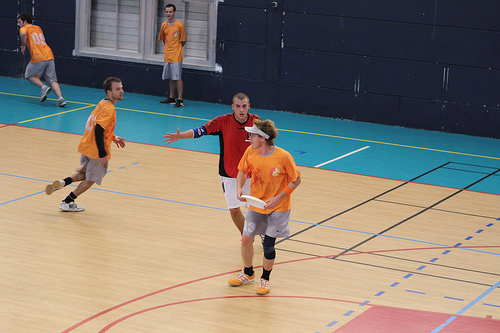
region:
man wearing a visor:
[227, 122, 307, 318]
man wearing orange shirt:
[226, 120, 296, 300]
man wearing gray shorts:
[230, 120, 305, 300]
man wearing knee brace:
[215, 111, 315, 311]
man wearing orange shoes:
[226, 122, 297, 292]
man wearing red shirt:
[177, 100, 232, 225]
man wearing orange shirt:
[45, 70, 137, 260]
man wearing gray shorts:
[33, 72, 133, 210]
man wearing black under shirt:
[46, 66, 124, 241]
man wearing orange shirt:
[140, 5, 200, 112]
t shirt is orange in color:
[231, 149, 310, 209]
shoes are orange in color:
[234, 262, 290, 302]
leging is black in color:
[253, 228, 295, 261]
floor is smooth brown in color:
[98, 230, 169, 302]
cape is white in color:
[246, 114, 274, 146]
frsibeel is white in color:
[232, 184, 261, 214]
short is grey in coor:
[65, 159, 120, 184]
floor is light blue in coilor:
[366, 138, 397, 170]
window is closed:
[91, 9, 230, 63]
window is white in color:
[73, 1, 169, 70]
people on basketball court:
[4, 2, 322, 303]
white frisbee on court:
[235, 193, 271, 211]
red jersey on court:
[203, 108, 262, 171]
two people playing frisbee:
[160, 95, 327, 280]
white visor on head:
[239, 120, 267, 143]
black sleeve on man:
[90, 125, 106, 161]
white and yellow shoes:
[238, 267, 271, 297]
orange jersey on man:
[235, 150, 299, 220]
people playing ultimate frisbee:
[160, 105, 337, 297]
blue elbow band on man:
[196, 120, 207, 140]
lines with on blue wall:
[7, 3, 493, 133]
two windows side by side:
[74, 1, 216, 72]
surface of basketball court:
[2, 71, 496, 330]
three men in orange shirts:
[15, 4, 184, 214]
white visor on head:
[243, 120, 277, 151]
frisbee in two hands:
[237, 187, 270, 212]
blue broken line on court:
[322, 218, 497, 329]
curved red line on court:
[99, 292, 371, 331]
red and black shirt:
[204, 110, 262, 176]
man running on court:
[42, 75, 129, 212]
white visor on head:
[223, 120, 298, 159]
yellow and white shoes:
[221, 258, 318, 327]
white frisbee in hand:
[210, 184, 290, 238]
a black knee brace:
[251, 231, 292, 274]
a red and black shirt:
[188, 99, 272, 196]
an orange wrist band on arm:
[276, 181, 306, 206]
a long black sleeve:
[87, 114, 121, 166]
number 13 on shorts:
[233, 212, 265, 243]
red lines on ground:
[67, 231, 489, 332]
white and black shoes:
[47, 174, 99, 221]